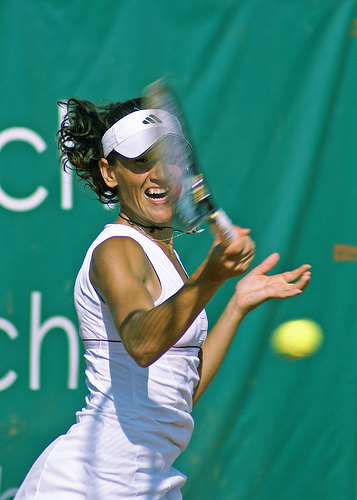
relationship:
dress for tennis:
[13, 221, 206, 496] [4, 102, 230, 499]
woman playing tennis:
[30, 83, 357, 493] [4, 102, 230, 499]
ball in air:
[270, 317, 323, 358] [257, 311, 347, 360]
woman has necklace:
[119, 194, 206, 241] [112, 212, 217, 246]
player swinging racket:
[138, 77, 340, 367] [128, 63, 291, 302]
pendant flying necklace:
[117, 199, 253, 236] [112, 212, 217, 246]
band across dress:
[78, 326, 218, 362] [72, 335, 217, 353]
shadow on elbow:
[114, 307, 195, 370] [116, 321, 173, 369]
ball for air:
[270, 317, 323, 358] [257, 311, 347, 360]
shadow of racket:
[114, 307, 195, 370] [109, 303, 210, 354]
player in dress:
[4, 102, 230, 499] [13, 221, 206, 496]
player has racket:
[138, 77, 340, 367] [128, 63, 291, 302]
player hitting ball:
[11, 94, 312, 498] [270, 317, 323, 358]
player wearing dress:
[4, 102, 230, 499] [13, 221, 206, 496]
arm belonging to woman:
[89, 224, 256, 368] [12, 96, 313, 495]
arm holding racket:
[89, 224, 256, 368] [142, 74, 238, 246]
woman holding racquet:
[12, 96, 313, 495] [144, 73, 238, 248]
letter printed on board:
[1, 315, 17, 393] [1, 2, 345, 498]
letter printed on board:
[29, 288, 78, 389] [1, 2, 345, 498]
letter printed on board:
[1, 126, 47, 213] [1, 2, 345, 498]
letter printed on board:
[57, 98, 115, 210] [1, 2, 345, 498]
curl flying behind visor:
[67, 113, 93, 138] [102, 109, 194, 160]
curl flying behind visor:
[97, 190, 119, 199] [102, 109, 194, 160]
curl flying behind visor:
[62, 96, 86, 112] [102, 109, 194, 160]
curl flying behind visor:
[58, 140, 75, 148] [102, 109, 194, 160]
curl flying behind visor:
[59, 114, 75, 125] [102, 109, 194, 160]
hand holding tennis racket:
[192, 204, 270, 273] [143, 75, 239, 247]